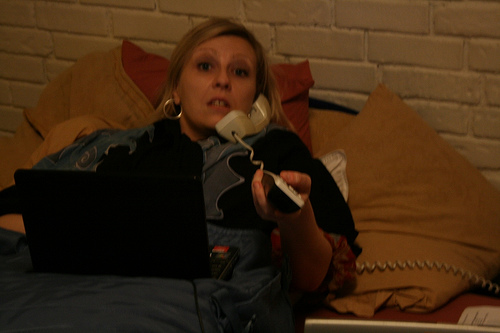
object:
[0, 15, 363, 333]
woman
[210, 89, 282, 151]
phone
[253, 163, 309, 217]
remote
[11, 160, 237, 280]
computer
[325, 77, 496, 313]
case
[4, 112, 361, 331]
shirt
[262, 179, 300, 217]
bottom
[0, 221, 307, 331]
blanket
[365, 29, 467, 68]
brick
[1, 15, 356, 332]
person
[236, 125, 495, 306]
cord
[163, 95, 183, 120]
hoop earring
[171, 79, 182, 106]
ear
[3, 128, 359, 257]
design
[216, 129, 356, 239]
shoulders